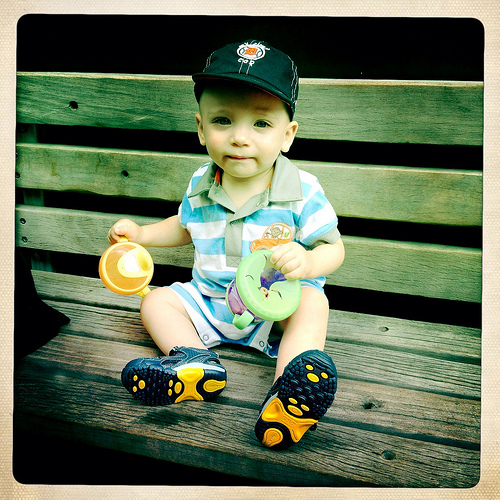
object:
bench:
[16, 72, 480, 489]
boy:
[107, 41, 344, 447]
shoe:
[254, 349, 337, 451]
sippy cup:
[99, 236, 154, 295]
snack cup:
[227, 251, 300, 330]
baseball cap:
[193, 43, 300, 109]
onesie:
[178, 161, 337, 357]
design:
[250, 223, 295, 253]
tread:
[285, 370, 327, 408]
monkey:
[271, 227, 282, 236]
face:
[206, 95, 282, 177]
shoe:
[121, 347, 227, 406]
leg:
[141, 287, 207, 357]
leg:
[274, 288, 329, 387]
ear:
[282, 121, 299, 152]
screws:
[19, 218, 26, 224]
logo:
[236, 44, 265, 60]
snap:
[203, 335, 209, 340]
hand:
[108, 218, 142, 243]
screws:
[21, 237, 27, 243]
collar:
[187, 154, 302, 202]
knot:
[364, 402, 373, 409]